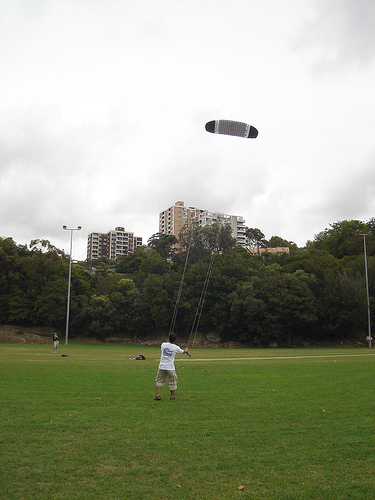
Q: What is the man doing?
A: Flying a kite.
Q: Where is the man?
A: In a park.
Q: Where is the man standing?
A: In grass.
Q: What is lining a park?
A: A dense area of trees.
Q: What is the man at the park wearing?
A: A white shirt.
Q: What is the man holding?
A: A large kite.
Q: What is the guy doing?
A: Flying a kite.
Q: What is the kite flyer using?
A: Four strings.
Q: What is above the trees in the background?
A: Buildings.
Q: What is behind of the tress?
A: Large apartment buildings.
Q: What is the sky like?
A: Gray, cloudy, and dull.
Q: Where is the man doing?
A: Flying a kite.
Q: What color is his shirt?
A: White.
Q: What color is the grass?
A: Green.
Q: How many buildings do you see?
A: 2.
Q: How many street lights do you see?
A: Two.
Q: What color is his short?
A: Beige.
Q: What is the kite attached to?
A: Strings.